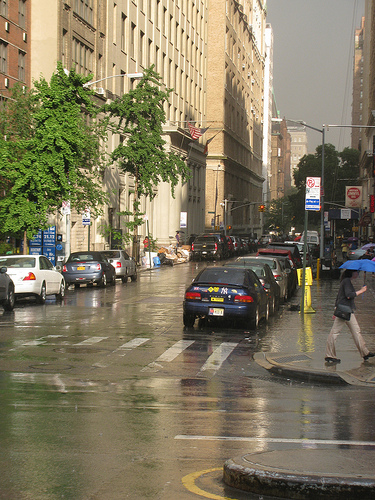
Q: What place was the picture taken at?
A: It was taken at the street.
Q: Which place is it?
A: It is a street.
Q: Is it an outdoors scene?
A: Yes, it is outdoors.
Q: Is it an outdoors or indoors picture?
A: It is outdoors.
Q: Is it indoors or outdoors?
A: It is outdoors.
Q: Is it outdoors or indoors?
A: It is outdoors.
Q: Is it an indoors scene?
A: No, it is outdoors.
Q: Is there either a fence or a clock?
A: No, there are no fences or clocks.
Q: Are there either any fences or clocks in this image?
A: No, there are no fences or clocks.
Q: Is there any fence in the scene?
A: No, there are no fences.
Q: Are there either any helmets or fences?
A: No, there are no fences or helmets.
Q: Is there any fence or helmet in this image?
A: No, there are no fences or helmets.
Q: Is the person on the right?
A: Yes, the person is on the right of the image.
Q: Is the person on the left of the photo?
A: No, the person is on the right of the image.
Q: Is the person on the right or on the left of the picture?
A: The person is on the right of the image.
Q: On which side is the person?
A: The person is on the right of the image.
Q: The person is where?
A: The person is on the sidewalk.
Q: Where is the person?
A: The person is on the sidewalk.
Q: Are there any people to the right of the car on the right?
A: Yes, there is a person to the right of the car.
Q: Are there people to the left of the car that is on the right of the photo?
A: No, the person is to the right of the car.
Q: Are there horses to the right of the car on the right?
A: No, there is a person to the right of the car.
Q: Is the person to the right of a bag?
A: No, the person is to the right of a car.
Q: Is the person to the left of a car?
A: No, the person is to the right of a car.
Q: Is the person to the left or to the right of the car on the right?
A: The person is to the right of the car.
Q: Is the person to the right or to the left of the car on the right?
A: The person is to the right of the car.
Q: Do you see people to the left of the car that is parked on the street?
A: No, the person is to the right of the car.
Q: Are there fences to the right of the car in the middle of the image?
A: No, there is a person to the right of the car.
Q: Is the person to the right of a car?
A: Yes, the person is to the right of a car.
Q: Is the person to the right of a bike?
A: No, the person is to the right of a car.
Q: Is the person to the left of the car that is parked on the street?
A: No, the person is to the right of the car.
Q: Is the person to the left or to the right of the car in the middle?
A: The person is to the right of the car.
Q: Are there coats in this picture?
A: No, there are no coats.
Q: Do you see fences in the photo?
A: No, there are no fences.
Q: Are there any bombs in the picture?
A: No, there are no bombs.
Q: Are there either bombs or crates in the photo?
A: No, there are no bombs or crates.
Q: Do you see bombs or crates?
A: No, there are no bombs or crates.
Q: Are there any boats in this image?
A: No, there are no boats.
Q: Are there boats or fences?
A: No, there are no boats or fences.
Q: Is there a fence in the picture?
A: No, there are no fences.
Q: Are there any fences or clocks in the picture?
A: No, there are no fences or clocks.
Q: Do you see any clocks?
A: No, there are no clocks.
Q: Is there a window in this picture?
A: Yes, there is a window.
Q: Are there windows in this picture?
A: Yes, there is a window.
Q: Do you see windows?
A: Yes, there is a window.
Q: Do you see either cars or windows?
A: Yes, there is a window.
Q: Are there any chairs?
A: No, there are no chairs.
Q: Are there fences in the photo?
A: No, there are no fences.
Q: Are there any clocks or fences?
A: No, there are no fences or clocks.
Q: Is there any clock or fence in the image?
A: No, there are no fences or clocks.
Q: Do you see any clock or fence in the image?
A: No, there are no fences or clocks.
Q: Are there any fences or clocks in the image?
A: No, there are no fences or clocks.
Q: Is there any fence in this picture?
A: No, there are no fences.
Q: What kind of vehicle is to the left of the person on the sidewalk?
A: The vehicle is a car.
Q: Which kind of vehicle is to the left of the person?
A: The vehicle is a car.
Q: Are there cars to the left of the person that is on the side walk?
A: Yes, there is a car to the left of the person.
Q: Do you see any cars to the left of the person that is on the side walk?
A: Yes, there is a car to the left of the person.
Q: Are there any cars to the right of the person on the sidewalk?
A: No, the car is to the left of the person.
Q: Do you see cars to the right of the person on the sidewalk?
A: No, the car is to the left of the person.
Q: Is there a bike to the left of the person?
A: No, there is a car to the left of the person.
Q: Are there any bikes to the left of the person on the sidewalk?
A: No, there is a car to the left of the person.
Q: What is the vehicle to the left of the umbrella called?
A: The vehicle is a car.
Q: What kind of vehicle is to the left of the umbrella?
A: The vehicle is a car.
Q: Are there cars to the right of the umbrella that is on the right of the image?
A: No, the car is to the left of the umbrella.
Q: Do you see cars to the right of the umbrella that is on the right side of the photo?
A: No, the car is to the left of the umbrella.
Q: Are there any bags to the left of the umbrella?
A: No, there is a car to the left of the umbrella.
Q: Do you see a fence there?
A: No, there are no fences.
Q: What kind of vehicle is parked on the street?
A: The vehicle is a car.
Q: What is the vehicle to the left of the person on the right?
A: The vehicle is a car.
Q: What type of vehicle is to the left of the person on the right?
A: The vehicle is a car.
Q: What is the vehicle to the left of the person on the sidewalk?
A: The vehicle is a car.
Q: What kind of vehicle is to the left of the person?
A: The vehicle is a car.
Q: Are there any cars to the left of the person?
A: Yes, there is a car to the left of the person.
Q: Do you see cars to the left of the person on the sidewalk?
A: Yes, there is a car to the left of the person.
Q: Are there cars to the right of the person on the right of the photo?
A: No, the car is to the left of the person.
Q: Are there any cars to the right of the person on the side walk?
A: No, the car is to the left of the person.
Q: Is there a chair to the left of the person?
A: No, there is a car to the left of the person.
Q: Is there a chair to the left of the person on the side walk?
A: No, there is a car to the left of the person.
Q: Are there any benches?
A: No, there are no benches.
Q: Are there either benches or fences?
A: No, there are no benches or fences.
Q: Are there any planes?
A: No, there are no planes.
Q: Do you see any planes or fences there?
A: No, there are no planes or fences.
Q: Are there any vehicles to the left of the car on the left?
A: Yes, there is a vehicle to the left of the car.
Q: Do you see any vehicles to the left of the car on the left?
A: Yes, there is a vehicle to the left of the car.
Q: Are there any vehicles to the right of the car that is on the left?
A: No, the vehicle is to the left of the car.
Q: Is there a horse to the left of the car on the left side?
A: No, there is a vehicle to the left of the car.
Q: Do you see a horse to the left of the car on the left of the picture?
A: No, there is a vehicle to the left of the car.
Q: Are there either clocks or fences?
A: No, there are no fences or clocks.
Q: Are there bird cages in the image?
A: No, there are no bird cages.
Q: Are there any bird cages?
A: No, there are no bird cages.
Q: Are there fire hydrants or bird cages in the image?
A: No, there are no bird cages or fire hydrants.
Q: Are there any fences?
A: No, there are no fences.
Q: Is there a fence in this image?
A: No, there are no fences.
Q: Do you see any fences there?
A: No, there are no fences.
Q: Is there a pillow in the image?
A: No, there are no pillows.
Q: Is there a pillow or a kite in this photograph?
A: No, there are no pillows or kites.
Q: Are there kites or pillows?
A: No, there are no pillows or kites.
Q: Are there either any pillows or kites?
A: No, there are no pillows or kites.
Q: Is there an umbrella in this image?
A: Yes, there is an umbrella.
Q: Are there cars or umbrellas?
A: Yes, there is an umbrella.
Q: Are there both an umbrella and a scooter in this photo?
A: No, there is an umbrella but no scooters.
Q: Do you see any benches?
A: No, there are no benches.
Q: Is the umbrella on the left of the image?
A: No, the umbrella is on the right of the image.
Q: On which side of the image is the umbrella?
A: The umbrella is on the right of the image.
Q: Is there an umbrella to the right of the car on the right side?
A: Yes, there is an umbrella to the right of the car.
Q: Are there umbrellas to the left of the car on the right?
A: No, the umbrella is to the right of the car.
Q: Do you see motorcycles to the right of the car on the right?
A: No, there is an umbrella to the right of the car.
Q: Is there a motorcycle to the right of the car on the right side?
A: No, there is an umbrella to the right of the car.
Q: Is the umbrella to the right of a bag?
A: No, the umbrella is to the right of a car.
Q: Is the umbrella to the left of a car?
A: No, the umbrella is to the right of a car.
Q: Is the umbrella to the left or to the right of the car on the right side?
A: The umbrella is to the right of the car.